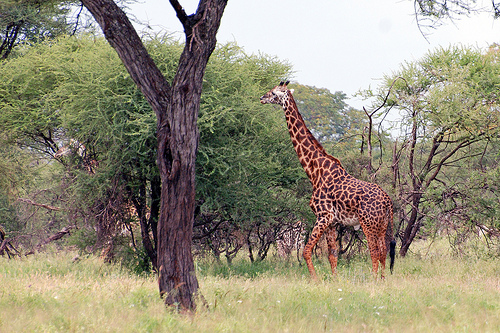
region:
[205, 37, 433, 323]
a giraffe in a field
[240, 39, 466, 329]
a giraffe walking in a field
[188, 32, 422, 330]
a giraffe walking on grass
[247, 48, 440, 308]
a giraffe walking in a grassy area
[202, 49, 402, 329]
a giraffe walking next to trees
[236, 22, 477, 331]
a giraffe walking outside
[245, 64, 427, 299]
a giraffe walking forward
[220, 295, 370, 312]
a field of green grass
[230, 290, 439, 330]
a green grass field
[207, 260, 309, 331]
an area with green grass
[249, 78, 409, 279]
giraffe walking through the grass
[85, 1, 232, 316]
tree trunk in the foreground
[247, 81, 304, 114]
giraffe's face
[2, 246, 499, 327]
grassy are the giraffe is walking through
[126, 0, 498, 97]
patch of blue sky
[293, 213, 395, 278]
the legs of the giraffe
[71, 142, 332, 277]
the group of giraffes behind the trees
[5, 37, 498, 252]
group of trees in background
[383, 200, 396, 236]
tail of the giraffe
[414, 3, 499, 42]
branches at top of screen barely visible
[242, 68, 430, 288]
the giraffe in the field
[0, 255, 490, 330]
a field of grass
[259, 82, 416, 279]
the giraffe is spotted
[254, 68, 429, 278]
the spots are brown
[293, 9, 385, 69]
the clear blue sky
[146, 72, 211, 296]
the tree trunk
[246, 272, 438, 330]
the grass is tall and dry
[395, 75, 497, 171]
the trees with green leaves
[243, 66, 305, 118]
the head of the giraffe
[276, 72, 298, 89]
the ossicones on the head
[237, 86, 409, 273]
giraffe is in field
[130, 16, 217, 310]
brown tree trunk in front of giraffe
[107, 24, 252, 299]
trunk splits into two branches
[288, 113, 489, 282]
giraffe has dark brown spots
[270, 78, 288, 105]
giraffe has white head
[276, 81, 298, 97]
giraffe has white ears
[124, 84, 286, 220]
green trees near giraffe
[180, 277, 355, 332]
grass is tall and yellow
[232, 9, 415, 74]
sky is grey and cloudy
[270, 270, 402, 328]
white weeds in grass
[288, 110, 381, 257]
colors on giraffe are brown and tan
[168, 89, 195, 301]
the tree bark is gray/brown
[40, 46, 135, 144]
the tree has green leaves on it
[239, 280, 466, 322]
the field the giraffe is standing in is light green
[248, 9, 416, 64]
the sky is white up above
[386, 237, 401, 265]
th etail on the giaraffe is black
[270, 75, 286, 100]
the giaraffe has horn type bumps on his next to ears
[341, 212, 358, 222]
the under belly of giaraffe is white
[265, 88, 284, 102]
the giaraffe has long eye lashes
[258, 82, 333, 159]
the giaraffe has a long neck to reach the leaves on the tree's